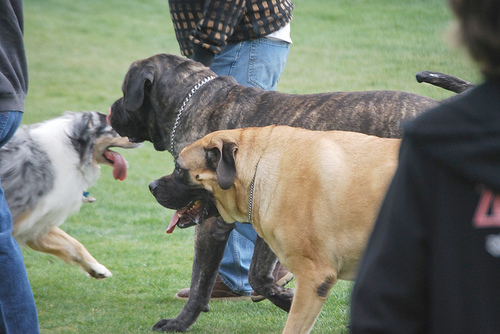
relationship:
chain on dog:
[170, 74, 215, 153] [108, 53, 447, 166]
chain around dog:
[247, 164, 256, 224] [148, 124, 405, 334]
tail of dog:
[416, 66, 475, 94] [108, 53, 447, 166]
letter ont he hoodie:
[471, 188, 494, 228] [349, 83, 500, 333]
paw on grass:
[152, 319, 186, 332] [21, 0, 197, 334]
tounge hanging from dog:
[109, 149, 126, 181] [1, 109, 142, 281]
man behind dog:
[166, 0, 293, 86] [108, 53, 447, 166]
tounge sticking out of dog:
[109, 149, 126, 181] [1, 109, 142, 281]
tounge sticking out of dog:
[167, 205, 189, 233] [148, 124, 405, 334]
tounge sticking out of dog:
[106, 105, 111, 125] [108, 53, 447, 166]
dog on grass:
[148, 124, 405, 334] [21, 0, 197, 334]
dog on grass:
[108, 53, 447, 166] [21, 0, 197, 334]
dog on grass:
[1, 109, 142, 281] [21, 0, 197, 334]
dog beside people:
[148, 124, 405, 334] [346, 0, 499, 334]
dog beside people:
[1, 109, 142, 281] [1, 0, 43, 332]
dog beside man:
[108, 53, 447, 166] [166, 0, 293, 86]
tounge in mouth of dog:
[167, 205, 189, 233] [148, 124, 405, 334]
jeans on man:
[214, 35, 288, 91] [166, 0, 293, 86]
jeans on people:
[1, 112, 37, 333] [1, 0, 43, 332]